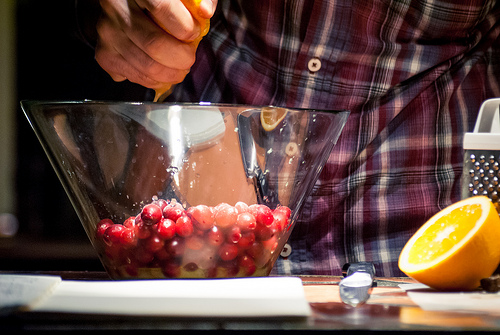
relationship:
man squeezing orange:
[92, 0, 500, 275] [110, 0, 203, 83]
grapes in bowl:
[78, 180, 299, 280] [4, 92, 357, 302]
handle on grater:
[453, 85, 498, 155] [448, 90, 498, 199]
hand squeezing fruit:
[107, 0, 220, 108] [115, 3, 269, 130]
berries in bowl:
[83, 183, 294, 272] [9, 77, 357, 297]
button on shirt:
[308, 58, 323, 72] [39, 8, 439, 270]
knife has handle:
[332, 249, 382, 312] [341, 253, 385, 283]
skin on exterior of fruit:
[418, 200, 494, 263] [394, 191, 497, 286]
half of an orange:
[392, 185, 498, 284] [398, 186, 499, 293]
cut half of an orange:
[151, 10, 208, 107] [145, 3, 220, 114]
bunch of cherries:
[93, 175, 300, 278] [77, 181, 303, 281]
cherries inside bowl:
[88, 171, 288, 296] [2, 62, 354, 292]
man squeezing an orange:
[92, 0, 500, 275] [106, 15, 235, 105]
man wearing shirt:
[92, 0, 500, 275] [197, 8, 477, 275]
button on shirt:
[308, 58, 323, 72] [214, 14, 484, 288]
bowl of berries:
[26, 74, 340, 307] [97, 188, 275, 276]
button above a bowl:
[298, 53, 328, 81] [34, 71, 348, 271]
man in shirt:
[15, 5, 396, 275] [193, 8, 400, 216]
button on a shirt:
[276, 240, 298, 264] [197, 8, 477, 275]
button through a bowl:
[274, 130, 312, 175] [24, 76, 333, 278]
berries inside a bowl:
[97, 199, 293, 278] [9, 77, 357, 297]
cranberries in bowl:
[84, 180, 292, 305] [17, 104, 375, 298]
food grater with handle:
[459, 96, 499, 215] [457, 115, 497, 152]